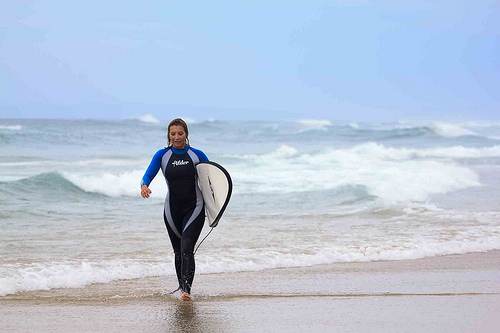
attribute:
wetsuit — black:
[153, 154, 204, 296]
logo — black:
[199, 167, 234, 201]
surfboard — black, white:
[184, 153, 246, 240]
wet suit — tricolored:
[139, 117, 210, 301]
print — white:
[167, 157, 193, 170]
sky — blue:
[216, 11, 498, 111]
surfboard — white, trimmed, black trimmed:
[196, 160, 233, 227]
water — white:
[0, 112, 499, 296]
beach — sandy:
[1, 248, 498, 331]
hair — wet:
[165, 118, 189, 146]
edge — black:
[198, 161, 234, 226]